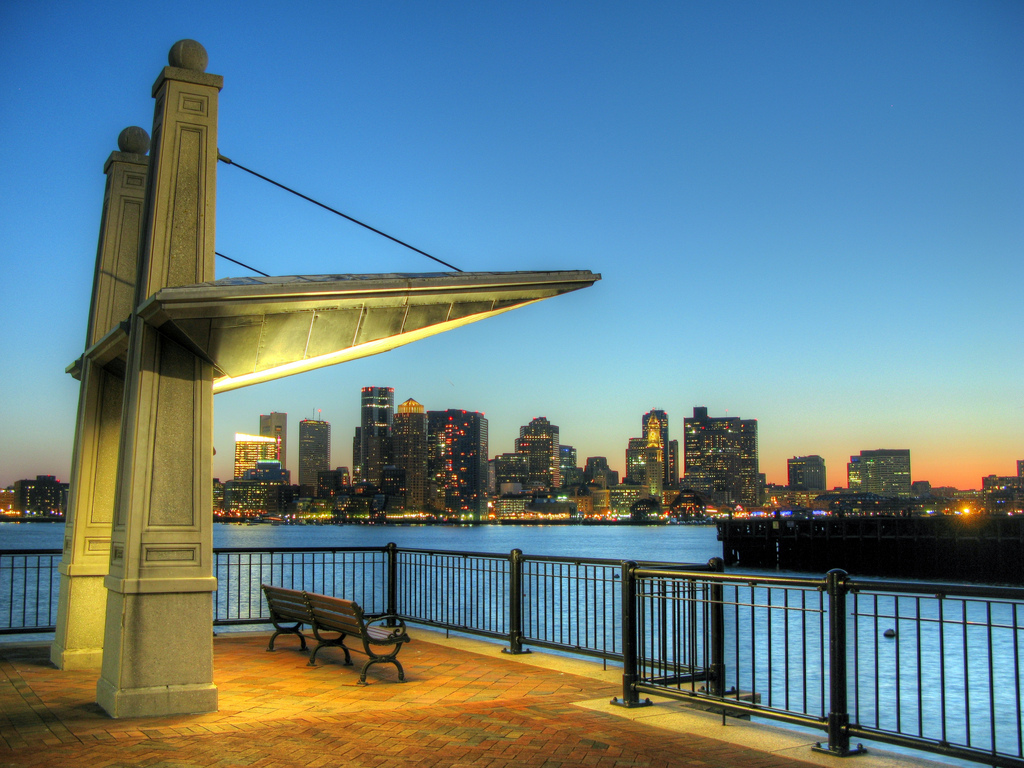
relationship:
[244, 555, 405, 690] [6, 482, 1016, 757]
bench overlooking river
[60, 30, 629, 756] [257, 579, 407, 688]
structure over bench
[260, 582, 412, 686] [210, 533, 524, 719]
bench in a dock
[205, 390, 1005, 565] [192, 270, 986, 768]
big city in background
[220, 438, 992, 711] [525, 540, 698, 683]
calm light blue water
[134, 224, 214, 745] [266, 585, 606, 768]
concrete columns on a dock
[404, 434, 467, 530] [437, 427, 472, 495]
building with red lights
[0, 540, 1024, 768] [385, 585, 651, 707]
fence on a dock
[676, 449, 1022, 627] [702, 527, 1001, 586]
boat on calm water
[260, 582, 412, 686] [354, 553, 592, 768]
bench by a waterway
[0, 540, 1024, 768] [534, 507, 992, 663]
fence in front of water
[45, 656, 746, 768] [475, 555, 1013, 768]
concrete area by water for viewing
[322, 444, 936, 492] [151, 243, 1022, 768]
cityscape in distance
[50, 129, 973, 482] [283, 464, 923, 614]
sunset sky just as sun going down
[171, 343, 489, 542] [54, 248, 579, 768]
light emanating from a structure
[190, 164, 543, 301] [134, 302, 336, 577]
wires holding a heavy looking light structure up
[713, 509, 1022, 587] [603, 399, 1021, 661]
boat dark ship or other area by water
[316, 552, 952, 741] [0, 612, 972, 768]
fence at a dock